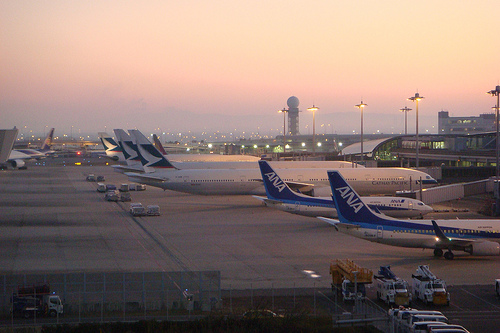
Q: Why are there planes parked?
A: Airport.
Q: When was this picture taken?
A: Sunset.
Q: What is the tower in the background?
A: Airplane tower.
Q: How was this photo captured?
A: An aerial shot.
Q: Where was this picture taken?
A: At the airport.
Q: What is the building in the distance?
A: The airport.